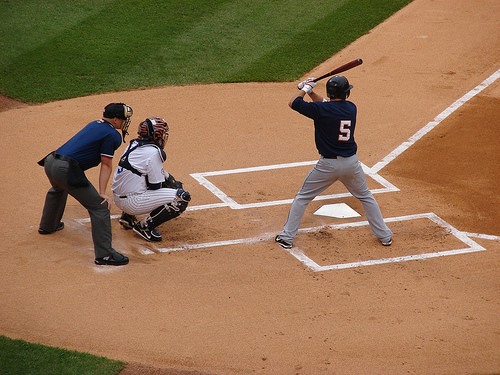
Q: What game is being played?
A: Baseball.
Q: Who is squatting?
A: Catcher.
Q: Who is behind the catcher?
A: Umpire.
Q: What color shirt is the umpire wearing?
A: Blue.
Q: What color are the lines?
A: White.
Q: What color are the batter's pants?
A: Gray.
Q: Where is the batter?
A: In the white box.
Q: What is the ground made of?
A: Dirt.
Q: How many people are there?
A: Three.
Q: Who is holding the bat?
A: The batter.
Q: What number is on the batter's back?
A: Five.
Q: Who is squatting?
A: The catcher.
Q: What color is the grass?
A: Green.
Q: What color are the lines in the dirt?
A: White.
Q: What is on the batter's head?
A: A helmet.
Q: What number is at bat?
A: 5.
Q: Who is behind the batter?
A: Catcher.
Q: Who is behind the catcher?
A: Umpire.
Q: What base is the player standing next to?
A: Home plate.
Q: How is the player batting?
A: Lefty.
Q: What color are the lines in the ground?
A: White.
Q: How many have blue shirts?
A: Two.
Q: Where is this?
A: Baseball field.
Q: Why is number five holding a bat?
A: To hit the ball.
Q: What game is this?
A: Baseball.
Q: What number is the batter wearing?
A: Five.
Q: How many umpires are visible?
A: One.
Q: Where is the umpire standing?
A: Behind the catcher.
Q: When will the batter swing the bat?
A: When the ball enters the strike zone.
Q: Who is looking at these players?
A: The photographer.